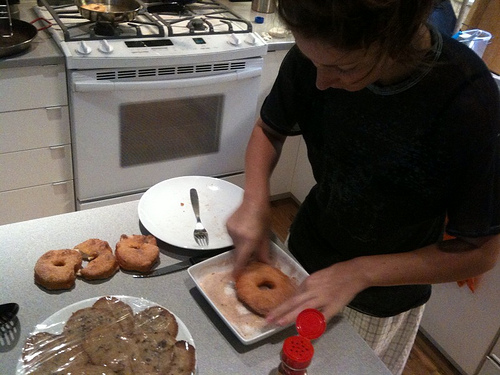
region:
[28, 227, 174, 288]
three brown donuts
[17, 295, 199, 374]
white plate covered by cookies wrapped in plastic wrap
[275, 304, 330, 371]
red plastic shaker top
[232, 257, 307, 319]
brown donut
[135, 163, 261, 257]
white plate with a metallic grey fork on top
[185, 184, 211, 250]
metallic grey fork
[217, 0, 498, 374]
woman wearing a black shirt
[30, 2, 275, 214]
white and grey stove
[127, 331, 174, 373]
brown cookie with dark chocolate chips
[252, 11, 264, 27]
blue bottle cap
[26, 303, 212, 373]
cookies on the plate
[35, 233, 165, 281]
coated orange donuts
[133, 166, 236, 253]
empty plate with fork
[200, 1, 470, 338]
lady coating donuts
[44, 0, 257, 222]
white stove with skillet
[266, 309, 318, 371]
seasoning with red cover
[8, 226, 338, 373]
food on the top of the counter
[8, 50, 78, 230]
gray counter top with white cabinets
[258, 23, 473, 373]
woman with black shirt coating donuts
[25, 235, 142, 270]
three donuts on top of the counter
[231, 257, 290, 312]
a donut being covered with sugar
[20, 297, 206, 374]
a plate of chocolate chip cookies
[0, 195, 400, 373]
a table that all the goodies are on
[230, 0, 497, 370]
a woman standing by the table and holding a donut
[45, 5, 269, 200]
a white stove with a pan on it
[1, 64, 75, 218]
a group of white cabinets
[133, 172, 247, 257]
a white plate with a fork in it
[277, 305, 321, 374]
a red lid with holes in it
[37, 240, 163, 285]
more donuts sitting on the table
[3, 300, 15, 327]
a spatula on the table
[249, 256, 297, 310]
the donut has cinnamon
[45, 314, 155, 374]
there are chocolate chip cookies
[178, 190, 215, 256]
a fork is on the plate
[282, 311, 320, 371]
shaker with a red top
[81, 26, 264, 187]
stove is white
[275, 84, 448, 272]
she is wearing a black shirt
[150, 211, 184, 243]
the plate is white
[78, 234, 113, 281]
there is a half donut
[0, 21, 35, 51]
pan on the counter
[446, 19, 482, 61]
there is a blue container in the background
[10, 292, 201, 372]
A plate of a brown pasty on a plate covered with saran wrap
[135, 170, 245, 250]
A silver fork on a white plate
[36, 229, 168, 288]
Three donuts on a counter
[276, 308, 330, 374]
A red container of a spice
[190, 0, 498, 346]
A woman working with a doughnut in a square dish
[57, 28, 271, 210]
A white stove with a window in the oven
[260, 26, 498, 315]
Woman wearing a black shirt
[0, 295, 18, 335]
The tip of a black cooking utensil with holes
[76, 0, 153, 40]
A doughnut in a pan on top of the stove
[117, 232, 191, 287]
A silver object around a doughnut